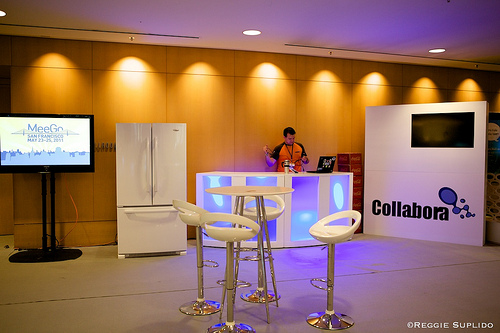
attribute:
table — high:
[198, 180, 304, 328]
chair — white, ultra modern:
[305, 204, 365, 267]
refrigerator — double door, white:
[112, 120, 192, 259]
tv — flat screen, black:
[2, 109, 97, 176]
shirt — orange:
[271, 139, 311, 168]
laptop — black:
[309, 152, 338, 175]